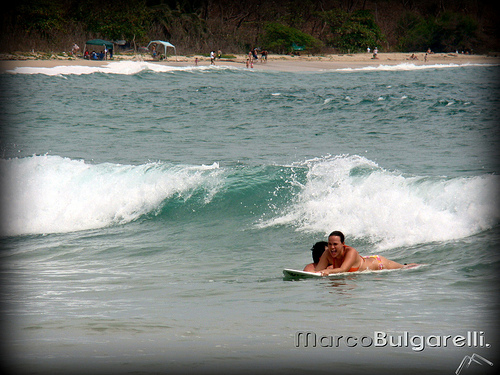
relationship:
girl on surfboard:
[319, 228, 412, 271] [279, 262, 428, 281]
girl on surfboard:
[311, 230, 423, 278] [276, 265, 427, 281]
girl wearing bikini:
[311, 230, 423, 278] [345, 248, 385, 274]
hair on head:
[325, 230, 343, 237] [327, 228, 347, 258]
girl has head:
[311, 230, 423, 278] [327, 228, 347, 258]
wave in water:
[301, 159, 467, 243] [15, 76, 497, 352]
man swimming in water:
[303, 236, 329, 273] [15, 76, 497, 352]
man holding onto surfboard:
[303, 240, 328, 272] [282, 262, 431, 278]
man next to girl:
[303, 240, 328, 272] [311, 230, 423, 278]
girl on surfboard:
[311, 230, 423, 278] [279, 259, 436, 282]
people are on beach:
[243, 42, 466, 65] [10, 29, 497, 86]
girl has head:
[311, 230, 423, 278] [311, 238, 332, 259]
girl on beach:
[311, 230, 423, 278] [10, 29, 497, 86]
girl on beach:
[311, 230, 423, 278] [4, 32, 497, 89]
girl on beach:
[311, 230, 423, 278] [4, 26, 491, 90]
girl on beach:
[311, 230, 423, 278] [6, 29, 491, 81]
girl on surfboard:
[311, 230, 423, 278] [282, 263, 426, 284]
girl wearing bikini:
[311, 230, 423, 278] [331, 245, 385, 272]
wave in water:
[242, 151, 500, 255] [28, 42, 454, 354]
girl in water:
[311, 230, 423, 278] [43, 51, 468, 349]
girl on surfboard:
[311, 230, 423, 278] [261, 244, 455, 300]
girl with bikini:
[311, 230, 423, 278] [338, 246, 371, 267]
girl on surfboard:
[311, 230, 423, 278] [277, 253, 389, 286]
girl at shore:
[311, 230, 423, 278] [182, 30, 429, 83]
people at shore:
[186, 39, 404, 72] [173, 43, 386, 70]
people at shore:
[188, 38, 361, 71] [175, 27, 388, 65]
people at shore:
[188, 23, 364, 69] [207, 32, 428, 68]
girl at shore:
[311, 230, 423, 278] [193, 35, 361, 74]